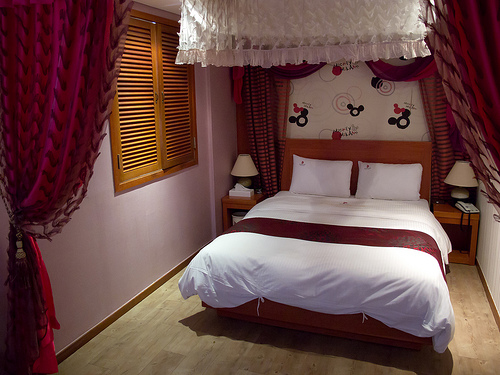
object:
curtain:
[0, 0, 136, 372]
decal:
[289, 103, 309, 128]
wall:
[244, 61, 471, 144]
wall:
[108, 212, 198, 246]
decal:
[346, 103, 365, 117]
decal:
[331, 65, 342, 77]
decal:
[330, 130, 343, 141]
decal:
[370, 77, 396, 97]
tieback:
[9, 215, 26, 233]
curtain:
[420, 0, 498, 221]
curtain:
[228, 23, 330, 195]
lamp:
[443, 160, 480, 201]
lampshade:
[229, 154, 259, 178]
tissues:
[225, 184, 252, 198]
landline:
[455, 200, 480, 214]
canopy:
[175, 0, 435, 67]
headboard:
[279, 139, 431, 205]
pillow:
[289, 155, 355, 196]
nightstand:
[429, 201, 483, 265]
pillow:
[354, 160, 423, 200]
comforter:
[177, 155, 462, 356]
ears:
[387, 116, 399, 125]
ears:
[288, 115, 296, 123]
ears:
[346, 102, 355, 110]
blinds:
[116, 18, 192, 178]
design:
[287, 91, 427, 141]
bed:
[199, 137, 455, 354]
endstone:
[432, 209, 480, 267]